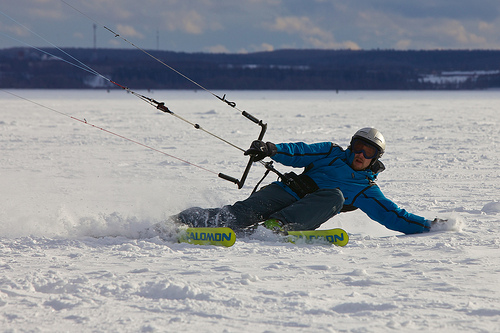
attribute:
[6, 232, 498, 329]
snow — white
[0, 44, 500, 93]
mountains — wooded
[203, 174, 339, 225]
pants — gray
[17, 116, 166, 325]
snow — white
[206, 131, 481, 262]
skier — towed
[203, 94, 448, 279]
man — silver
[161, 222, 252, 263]
ski — blue, yellow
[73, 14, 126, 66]
pole — blurry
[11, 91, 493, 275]
snow — white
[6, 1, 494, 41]
sky — blue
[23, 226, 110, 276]
snow — white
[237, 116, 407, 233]
coat — blue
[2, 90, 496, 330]
snow — white